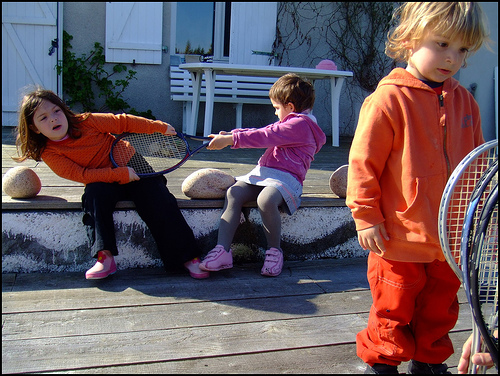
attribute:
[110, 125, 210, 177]
tennis racket — blue, red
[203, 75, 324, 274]
girl — fighting, playing tug of war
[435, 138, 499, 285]
tennis racket — together, grouped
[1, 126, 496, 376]
walkway — wooden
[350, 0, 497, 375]
boy — child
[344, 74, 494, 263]
jacket — orange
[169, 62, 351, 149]
table — white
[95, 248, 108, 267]
flower — red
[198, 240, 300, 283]
boots — pink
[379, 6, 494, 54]
hair — long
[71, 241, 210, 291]
sports shoes — pink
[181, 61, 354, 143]
bench — white, slatted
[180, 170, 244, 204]
stone — round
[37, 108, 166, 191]
shirt — orange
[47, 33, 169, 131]
plant — green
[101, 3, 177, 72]
shutter — open, mostly closed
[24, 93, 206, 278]
girl — fighting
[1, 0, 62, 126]
gate — wooden